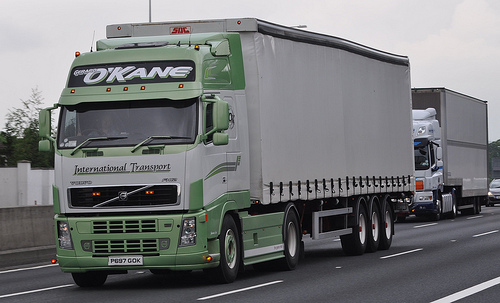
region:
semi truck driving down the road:
[42, 17, 431, 276]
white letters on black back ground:
[63, 60, 203, 95]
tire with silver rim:
[209, 210, 259, 273]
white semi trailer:
[242, 7, 432, 207]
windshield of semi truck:
[52, 95, 207, 153]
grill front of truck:
[80, 217, 185, 263]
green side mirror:
[197, 83, 234, 145]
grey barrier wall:
[12, 203, 53, 249]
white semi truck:
[413, 112, 457, 214]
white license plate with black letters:
[105, 249, 156, 270]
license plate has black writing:
[98, 245, 150, 270]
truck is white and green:
[12, 95, 292, 276]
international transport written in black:
[58, 155, 189, 197]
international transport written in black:
[66, 162, 176, 182]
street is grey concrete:
[245, 260, 499, 299]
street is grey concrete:
[322, 251, 497, 286]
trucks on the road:
[39, 23, 496, 297]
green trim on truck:
[42, 36, 237, 107]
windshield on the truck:
[54, 92, 201, 160]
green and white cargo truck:
[54, 16, 410, 261]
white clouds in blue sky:
[377, 22, 408, 42]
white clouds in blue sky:
[50, 9, 73, 30]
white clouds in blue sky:
[13, 37, 34, 54]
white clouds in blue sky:
[15, 44, 47, 63]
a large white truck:
[403, 86, 492, 212]